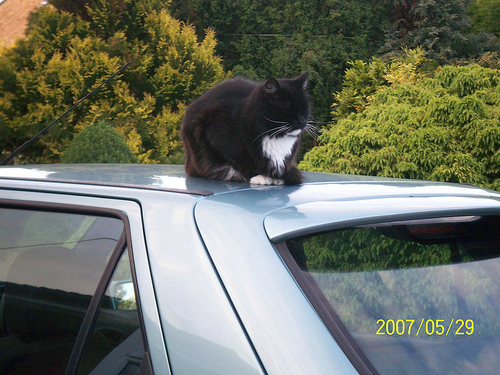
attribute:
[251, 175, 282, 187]
paws — white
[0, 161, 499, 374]
car — foreground, silver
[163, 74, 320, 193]
cat's mouth — white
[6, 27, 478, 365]
photo — daytime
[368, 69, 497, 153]
bushes — background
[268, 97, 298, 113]
eye — closed